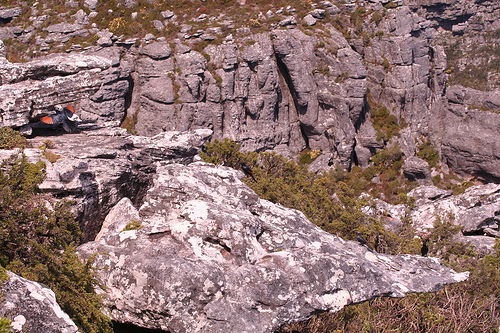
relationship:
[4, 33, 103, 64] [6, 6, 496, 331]
shrub on rocks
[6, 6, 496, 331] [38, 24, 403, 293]
rocks on mountain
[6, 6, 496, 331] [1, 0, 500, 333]
rocks on mountain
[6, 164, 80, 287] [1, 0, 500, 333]
trees on mountain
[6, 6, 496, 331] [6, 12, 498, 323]
rocks on mountain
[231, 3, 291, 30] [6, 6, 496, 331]
shrub on rocks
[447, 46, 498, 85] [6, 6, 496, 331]
green patch on rocks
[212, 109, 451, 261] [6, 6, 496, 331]
bushes between rocks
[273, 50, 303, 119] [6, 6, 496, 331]
shadow between rocks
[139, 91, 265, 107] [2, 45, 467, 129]
lines across rock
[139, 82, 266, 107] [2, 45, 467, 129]
lines across rock